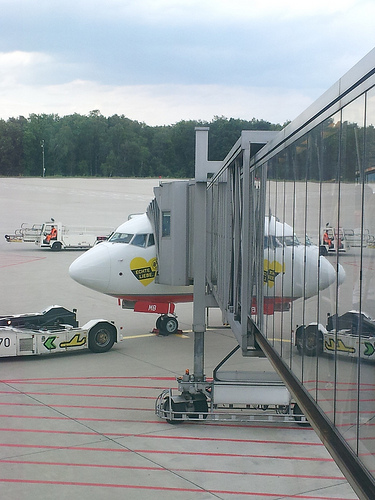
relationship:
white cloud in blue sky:
[76, 0, 374, 38] [0, 0, 374, 124]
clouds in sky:
[0, 53, 281, 126] [235, 3, 263, 19]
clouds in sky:
[0, 53, 281, 126] [1, 2, 374, 135]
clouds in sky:
[6, 63, 282, 126] [1, 2, 374, 135]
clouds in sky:
[0, 53, 281, 126] [29, 6, 374, 91]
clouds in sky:
[0, 53, 281, 126] [29, 17, 357, 98]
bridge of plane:
[143, 139, 374, 399] [177, 150, 368, 368]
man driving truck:
[43, 225, 59, 249] [31, 210, 100, 255]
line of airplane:
[231, 88, 375, 462] [68, 212, 339, 336]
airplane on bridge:
[68, 212, 339, 336] [138, 133, 373, 462]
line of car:
[231, 88, 375, 462] [315, 223, 367, 255]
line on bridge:
[231, 88, 375, 462] [149, 49, 374, 498]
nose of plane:
[68, 248, 109, 290] [53, 197, 209, 321]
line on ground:
[0, 377, 375, 500] [0, 173, 375, 500]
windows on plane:
[106, 228, 163, 254] [58, 181, 202, 317]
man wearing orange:
[44, 225, 57, 248] [44, 228, 57, 239]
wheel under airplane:
[155, 313, 178, 334] [67, 204, 193, 318]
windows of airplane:
[107, 231, 155, 250] [68, 212, 339, 336]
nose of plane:
[69, 245, 109, 291] [66, 213, 243, 333]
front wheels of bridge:
[159, 391, 206, 424] [219, 284, 345, 450]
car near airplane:
[0, 305, 125, 362] [68, 212, 339, 336]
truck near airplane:
[3, 219, 111, 252] [68, 212, 339, 336]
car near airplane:
[320, 221, 364, 256] [68, 212, 339, 336]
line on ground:
[0, 377, 375, 500] [1, 179, 373, 495]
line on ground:
[236, 140, 290, 363] [1, 179, 373, 495]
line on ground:
[3, 457, 345, 480] [1, 179, 373, 495]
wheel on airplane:
[155, 309, 182, 336] [38, 176, 275, 375]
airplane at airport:
[68, 212, 339, 336] [13, 122, 317, 487]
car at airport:
[1, 301, 125, 357] [20, 42, 332, 481]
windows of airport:
[250, 85, 374, 479] [1, 46, 370, 497]